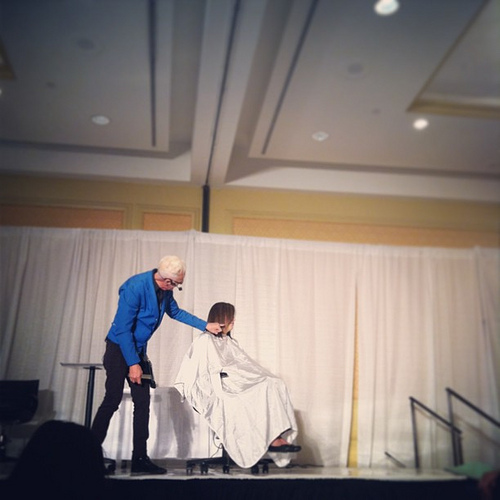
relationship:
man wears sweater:
[87, 252, 225, 476] [105, 267, 207, 366]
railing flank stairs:
[409, 386, 499, 467] [411, 388, 499, 493]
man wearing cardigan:
[64, 220, 239, 440] [109, 265, 182, 390]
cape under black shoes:
[177, 324, 310, 459] [270, 445, 302, 452]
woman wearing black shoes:
[173, 299, 301, 474] [272, 447, 302, 452]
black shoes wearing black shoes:
[272, 447, 302, 452] [127, 452, 163, 474]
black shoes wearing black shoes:
[272, 447, 302, 452] [99, 455, 119, 474]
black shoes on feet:
[99, 455, 119, 474] [269, 433, 299, 450]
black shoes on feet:
[272, 447, 302, 452] [130, 450, 167, 472]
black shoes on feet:
[272, 447, 302, 452] [99, 453, 116, 471]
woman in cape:
[173, 299, 301, 474] [174, 324, 300, 471]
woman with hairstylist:
[173, 299, 301, 474] [91, 255, 224, 475]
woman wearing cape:
[173, 299, 301, 474] [174, 324, 300, 471]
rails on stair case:
[402, 387, 429, 467] [406, 387, 498, 494]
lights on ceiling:
[410, 112, 439, 134] [239, 14, 495, 181]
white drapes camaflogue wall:
[1, 225, 498, 484] [4, 173, 488, 466]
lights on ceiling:
[391, 83, 444, 143] [14, 6, 484, 244]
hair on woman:
[204, 295, 233, 335] [183, 300, 300, 452]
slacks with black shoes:
[91, 338, 151, 455] [129, 452, 169, 474]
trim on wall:
[0, 169, 499, 253] [2, 201, 498, 249]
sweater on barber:
[94, 267, 214, 403] [63, 206, 200, 434]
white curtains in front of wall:
[9, 217, 498, 479] [1, 164, 498, 250]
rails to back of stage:
[402, 369, 490, 467] [4, 465, 471, 499]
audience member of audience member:
[5, 413, 118, 497] [5, 410, 118, 497]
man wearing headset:
[79, 246, 226, 475] [161, 273, 182, 302]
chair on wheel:
[179, 369, 303, 482] [261, 463, 271, 473]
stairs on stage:
[406, 395, 433, 493] [43, 222, 446, 498]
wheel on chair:
[261, 463, 271, 473] [183, 442, 276, 475]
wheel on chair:
[251, 465, 260, 475] [183, 442, 276, 475]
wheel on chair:
[219, 464, 232, 472] [183, 442, 276, 475]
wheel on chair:
[201, 465, 210, 475] [183, 442, 276, 475]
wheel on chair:
[186, 464, 196, 473] [183, 442, 276, 475]